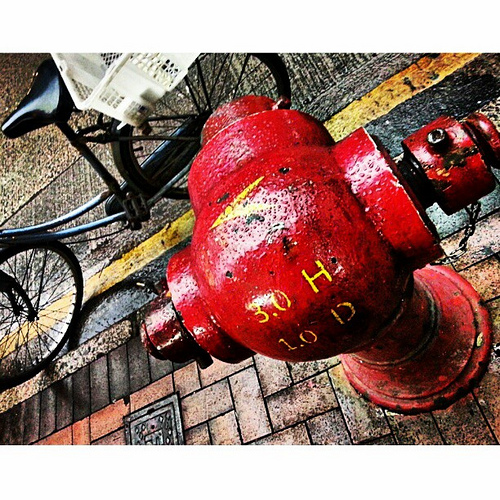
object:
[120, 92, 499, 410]
hydrant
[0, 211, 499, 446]
sidewalk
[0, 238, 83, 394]
wheel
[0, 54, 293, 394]
bicycle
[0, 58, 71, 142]
seat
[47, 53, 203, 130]
basket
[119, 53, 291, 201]
wheel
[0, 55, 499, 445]
road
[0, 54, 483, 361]
line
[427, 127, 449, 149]
bolt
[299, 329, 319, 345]
numbers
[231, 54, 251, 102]
spokes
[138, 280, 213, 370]
valve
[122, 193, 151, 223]
pedal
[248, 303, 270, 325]
3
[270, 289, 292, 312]
0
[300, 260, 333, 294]
h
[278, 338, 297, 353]
l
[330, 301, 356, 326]
d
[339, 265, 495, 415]
bottom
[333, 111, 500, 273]
side